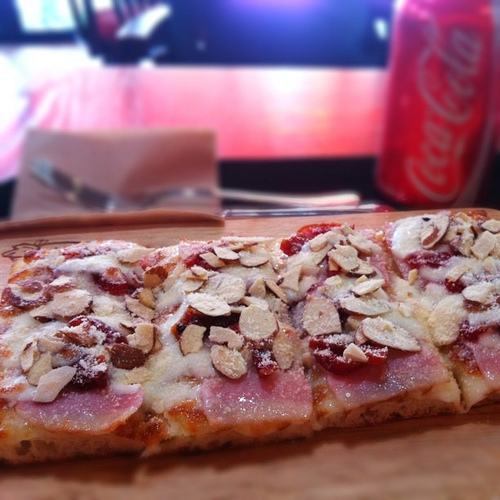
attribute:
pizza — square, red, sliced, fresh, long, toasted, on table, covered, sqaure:
[14, 246, 500, 405]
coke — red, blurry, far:
[394, 6, 484, 203]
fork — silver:
[36, 158, 354, 208]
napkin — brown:
[104, 145, 179, 166]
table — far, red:
[174, 64, 279, 116]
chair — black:
[74, 2, 166, 57]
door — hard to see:
[10, 12, 66, 46]